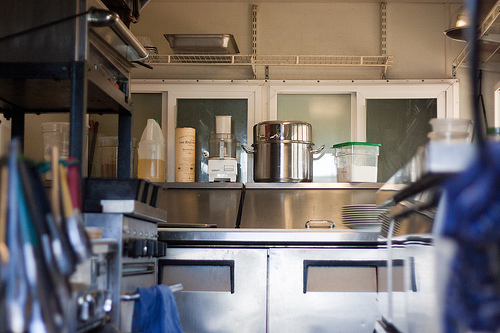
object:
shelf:
[147, 181, 412, 189]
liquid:
[137, 159, 168, 182]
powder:
[336, 163, 379, 183]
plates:
[342, 223, 390, 232]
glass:
[366, 99, 436, 184]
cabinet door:
[356, 85, 449, 182]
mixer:
[200, 114, 239, 183]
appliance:
[45, 197, 185, 331]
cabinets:
[351, 78, 458, 184]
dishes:
[339, 203, 377, 209]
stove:
[46, 211, 183, 333]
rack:
[137, 51, 394, 70]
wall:
[131, 1, 469, 80]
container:
[328, 141, 381, 184]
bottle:
[134, 117, 165, 182]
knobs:
[118, 237, 166, 258]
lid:
[145, 194, 438, 244]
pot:
[237, 119, 326, 183]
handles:
[237, 140, 255, 155]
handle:
[303, 143, 326, 155]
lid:
[330, 141, 383, 148]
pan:
[162, 33, 242, 66]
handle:
[303, 219, 335, 230]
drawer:
[240, 185, 378, 230]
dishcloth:
[127, 285, 183, 332]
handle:
[118, 280, 183, 304]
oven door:
[106, 257, 185, 332]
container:
[424, 116, 474, 134]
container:
[426, 129, 470, 145]